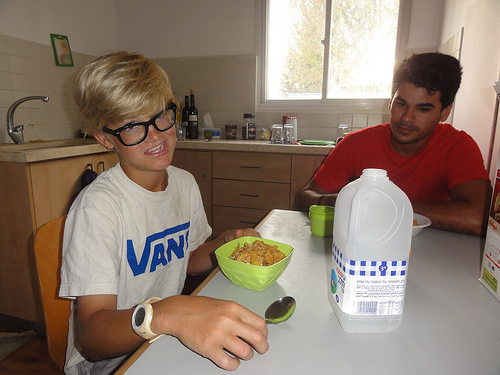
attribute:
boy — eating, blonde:
[78, 64, 211, 364]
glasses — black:
[105, 115, 183, 133]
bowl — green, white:
[244, 264, 266, 285]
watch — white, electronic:
[129, 306, 167, 350]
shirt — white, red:
[74, 171, 234, 288]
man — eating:
[324, 48, 470, 248]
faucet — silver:
[1, 72, 54, 172]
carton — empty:
[333, 176, 403, 345]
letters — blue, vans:
[122, 238, 192, 274]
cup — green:
[311, 207, 337, 235]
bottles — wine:
[178, 94, 204, 134]